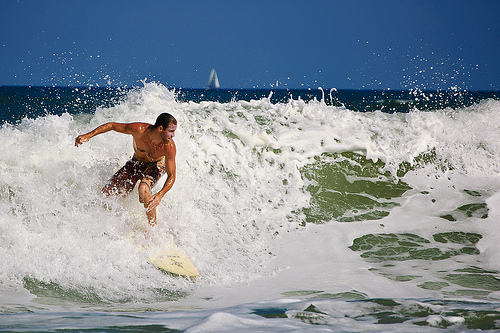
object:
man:
[72, 112, 179, 236]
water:
[1, 86, 498, 331]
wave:
[0, 95, 500, 315]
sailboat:
[204, 66, 222, 90]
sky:
[1, 0, 499, 89]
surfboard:
[93, 186, 205, 278]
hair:
[152, 112, 179, 134]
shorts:
[105, 156, 167, 198]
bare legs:
[136, 170, 160, 227]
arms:
[72, 120, 135, 147]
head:
[152, 111, 180, 143]